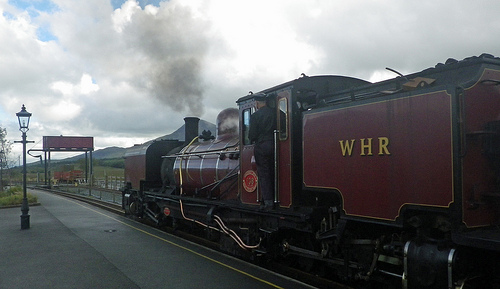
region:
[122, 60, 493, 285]
a choo choo train is on the tracks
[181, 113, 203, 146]
a smoke stack is on the engine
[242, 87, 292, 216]
the train engineer is standing in the engine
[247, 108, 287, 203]
the man is wearing all black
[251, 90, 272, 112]
the engineer has a cap on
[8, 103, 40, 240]
a lamp post is on the pavement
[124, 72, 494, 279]
the train is red with gold initials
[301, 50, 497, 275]
the coal car is behind the engine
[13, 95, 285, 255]
mountains are ahead of the train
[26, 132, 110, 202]
a water storage tank is ahead of the train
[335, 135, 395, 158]
The letters "WHR" on the train car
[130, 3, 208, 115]
Exhaust comes from the smokestack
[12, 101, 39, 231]
A lampost on the platform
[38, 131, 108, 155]
An overhead sign above the train tracks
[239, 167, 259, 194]
An emblem on a traincar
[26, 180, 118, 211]
a portion of the train tracks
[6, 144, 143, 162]
mountains in the distance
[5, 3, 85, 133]
a partly cloudy sky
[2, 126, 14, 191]
a tree by the sidewalk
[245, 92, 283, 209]
a man in the cab of the train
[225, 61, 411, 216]
The train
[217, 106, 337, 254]
The train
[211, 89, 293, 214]
The train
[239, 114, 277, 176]
The train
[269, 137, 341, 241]
The train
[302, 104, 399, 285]
The train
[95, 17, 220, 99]
black smoke coming out of smoke stack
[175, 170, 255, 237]
white line on the side of the train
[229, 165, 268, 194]
red and yellow round sign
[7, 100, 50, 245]
old fashioned light with black base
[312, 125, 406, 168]
yellow words on side of train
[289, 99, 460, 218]
red paint on train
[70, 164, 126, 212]
railings on side of platform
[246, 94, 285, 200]
man standing in the door of the train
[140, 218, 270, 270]
yellow line on the platform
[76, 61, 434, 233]
red train on the tracks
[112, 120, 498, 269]
Black and red train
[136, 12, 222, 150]
Smoke coming out of train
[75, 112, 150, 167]
Mountains in the background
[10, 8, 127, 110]
Sky is very cloudy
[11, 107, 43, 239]
Street lamp on the sidewalk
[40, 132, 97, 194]
Train stop for pedestrians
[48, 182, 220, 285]
Yellow line near track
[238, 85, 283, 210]
Conductor looking out the door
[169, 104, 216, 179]
Smoke stack on front of train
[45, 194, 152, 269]
Concrete poured sidewalk